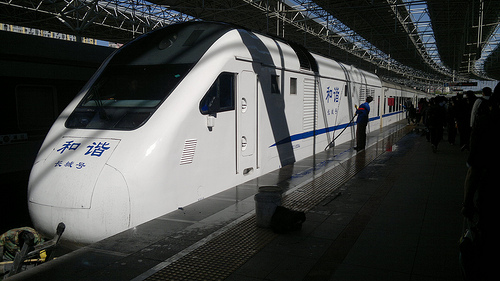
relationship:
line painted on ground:
[131, 117, 417, 280] [257, 117, 439, 279]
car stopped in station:
[26, 21, 437, 245] [4, 1, 498, 275]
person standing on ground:
[352, 97, 372, 152] [19, 121, 446, 275]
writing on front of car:
[53, 139, 111, 169] [26, 21, 437, 245]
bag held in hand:
[456, 211, 481, 275] [456, 201, 476, 225]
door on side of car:
[232, 59, 262, 179] [26, 21, 437, 245]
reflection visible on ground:
[351, 149, 371, 179] [9, 132, 472, 278]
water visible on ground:
[155, 115, 413, 248] [19, 121, 446, 275]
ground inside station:
[19, 121, 446, 275] [4, 1, 498, 275]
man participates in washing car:
[343, 93, 393, 166] [26, 21, 437, 245]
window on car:
[268, 70, 285, 100] [26, 21, 437, 245]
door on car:
[236, 70, 260, 175] [26, 21, 437, 245]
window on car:
[83, 43, 186, 110] [26, 21, 437, 245]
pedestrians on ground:
[343, 68, 374, 153] [19, 121, 446, 275]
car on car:
[23, 22, 383, 254] [26, 21, 437, 245]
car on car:
[26, 21, 437, 245] [26, 21, 437, 245]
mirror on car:
[205, 95, 219, 129] [26, 21, 437, 245]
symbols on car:
[57, 133, 114, 161] [26, 21, 437, 245]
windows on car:
[376, 91, 418, 118] [26, 21, 437, 245]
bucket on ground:
[253, 190, 283, 230] [19, 120, 446, 275]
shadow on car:
[244, 55, 317, 176] [26, 21, 437, 245]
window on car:
[386, 93, 392, 113] [26, 21, 437, 245]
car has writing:
[26, 21, 437, 245] [50, 138, 110, 175]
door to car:
[236, 70, 260, 175] [26, 21, 437, 245]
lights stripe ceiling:
[259, 10, 383, 59] [9, 0, 498, 74]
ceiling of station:
[9, 0, 498, 74] [4, 1, 498, 275]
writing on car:
[55, 137, 112, 159] [26, 21, 437, 245]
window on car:
[74, 64, 187, 129] [26, 21, 437, 245]